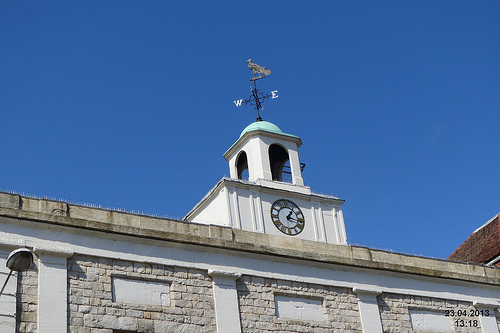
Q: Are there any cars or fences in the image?
A: No, there are no fences or cars.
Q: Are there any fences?
A: No, there are no fences.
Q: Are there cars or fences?
A: No, there are no fences or cars.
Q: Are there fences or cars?
A: No, there are no fences or cars.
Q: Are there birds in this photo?
A: Yes, there is a bird.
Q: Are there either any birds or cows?
A: Yes, there is a bird.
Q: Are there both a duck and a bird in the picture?
A: No, there is a bird but no ducks.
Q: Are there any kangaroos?
A: No, there are no kangaroos.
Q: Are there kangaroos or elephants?
A: No, there are no kangaroos or elephants.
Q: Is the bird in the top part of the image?
A: Yes, the bird is in the top of the image.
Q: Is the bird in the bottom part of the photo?
A: No, the bird is in the top of the image.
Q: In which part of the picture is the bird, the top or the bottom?
A: The bird is in the top of the image.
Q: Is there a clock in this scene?
A: Yes, there is a clock.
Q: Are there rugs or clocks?
A: Yes, there is a clock.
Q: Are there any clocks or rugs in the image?
A: Yes, there is a clock.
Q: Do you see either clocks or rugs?
A: Yes, there is a clock.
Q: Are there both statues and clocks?
A: No, there is a clock but no statues.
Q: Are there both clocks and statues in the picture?
A: No, there is a clock but no statues.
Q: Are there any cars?
A: No, there are no cars.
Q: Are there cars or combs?
A: No, there are no cars or combs.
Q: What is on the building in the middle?
A: The clock is on the tower.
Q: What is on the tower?
A: The clock is on the tower.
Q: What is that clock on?
A: The clock is on the tower.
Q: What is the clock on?
A: The clock is on the tower.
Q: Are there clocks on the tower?
A: Yes, there is a clock on the tower.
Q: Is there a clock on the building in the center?
A: Yes, there is a clock on the tower.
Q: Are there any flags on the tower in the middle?
A: No, there is a clock on the tower.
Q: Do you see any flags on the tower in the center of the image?
A: No, there is a clock on the tower.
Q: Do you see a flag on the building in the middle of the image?
A: No, there is a clock on the tower.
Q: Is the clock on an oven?
A: No, the clock is on the tower.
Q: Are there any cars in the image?
A: No, there are no cars.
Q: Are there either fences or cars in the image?
A: No, there are no cars or fences.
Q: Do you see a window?
A: Yes, there is a window.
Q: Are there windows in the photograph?
A: Yes, there is a window.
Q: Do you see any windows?
A: Yes, there is a window.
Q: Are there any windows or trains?
A: Yes, there is a window.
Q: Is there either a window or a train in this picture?
A: Yes, there is a window.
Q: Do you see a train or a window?
A: Yes, there is a window.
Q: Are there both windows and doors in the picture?
A: No, there is a window but no doors.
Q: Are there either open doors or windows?
A: Yes, there is an open window.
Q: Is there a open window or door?
A: Yes, there is an open window.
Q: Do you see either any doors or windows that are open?
A: Yes, the window is open.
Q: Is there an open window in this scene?
A: Yes, there is an open window.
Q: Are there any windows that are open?
A: Yes, there is a window that is open.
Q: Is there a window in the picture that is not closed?
A: Yes, there is a open window.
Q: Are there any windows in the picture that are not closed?
A: Yes, there is a open window.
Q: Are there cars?
A: No, there are no cars.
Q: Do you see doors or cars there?
A: No, there are no cars or doors.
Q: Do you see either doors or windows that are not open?
A: No, there is a window but it is open.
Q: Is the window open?
A: Yes, the window is open.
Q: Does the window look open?
A: Yes, the window is open.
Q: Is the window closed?
A: No, the window is open.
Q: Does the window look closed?
A: No, the window is open.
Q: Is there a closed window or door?
A: No, there is a window but it is open.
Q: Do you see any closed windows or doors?
A: No, there is a window but it is open.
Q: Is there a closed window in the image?
A: No, there is a window but it is open.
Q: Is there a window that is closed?
A: No, there is a window but it is open.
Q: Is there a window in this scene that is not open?
A: No, there is a window but it is open.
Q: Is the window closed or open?
A: The window is open.